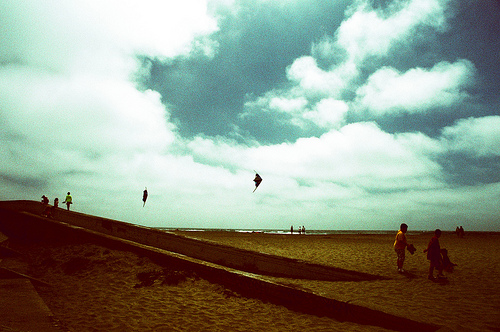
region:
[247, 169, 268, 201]
kite flying in the air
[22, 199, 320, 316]
sand hill in the beach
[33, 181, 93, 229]
people walking on sand hill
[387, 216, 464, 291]
people walking on the beach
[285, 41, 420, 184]
blue sky with white clouds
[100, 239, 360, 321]
large dark shadow on the sand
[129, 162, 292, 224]
two kites on the sky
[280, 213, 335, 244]
people walking in the distance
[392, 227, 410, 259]
person with yellow cotton shirt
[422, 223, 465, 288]
silhouette person on the beach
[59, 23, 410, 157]
lots of clouds in the sky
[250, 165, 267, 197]
a kite in the sky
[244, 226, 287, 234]
water at the edge of the sand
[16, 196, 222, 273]
ramp leading away from the beach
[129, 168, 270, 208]
two kites in the air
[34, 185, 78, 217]
people walking up the ramp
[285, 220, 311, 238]
people standing near the water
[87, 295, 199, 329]
sand at the beach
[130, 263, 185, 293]
weeds growing in the sand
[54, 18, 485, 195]
The sky is partly cloudy.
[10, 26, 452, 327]
It appears to be windy.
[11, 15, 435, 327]
This is on a beach.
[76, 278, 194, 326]
The ground here is sand.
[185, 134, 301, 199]
This is a kite.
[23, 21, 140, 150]
The clouds are white.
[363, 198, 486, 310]
The people are walking.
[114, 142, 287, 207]
The kites are silhouetted.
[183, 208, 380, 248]
There is water in the distance.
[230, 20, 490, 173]
The sky here is blue and white.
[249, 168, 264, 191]
Triangular kite flying in the sky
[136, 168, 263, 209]
Two kites flying in the sky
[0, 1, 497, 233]
White clouds in a bright blue sky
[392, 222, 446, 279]
Two people standing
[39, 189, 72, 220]
Group of people on a hill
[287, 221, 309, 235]
Three people on a shore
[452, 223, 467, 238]
Two people standing together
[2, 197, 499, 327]
Grassy area with concrete pathway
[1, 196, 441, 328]
Small incline with concrete paths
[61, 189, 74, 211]
Person in lime green shirt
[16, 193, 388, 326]
man made structure on beach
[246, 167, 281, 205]
kite flying above the beach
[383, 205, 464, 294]
people playing in the sand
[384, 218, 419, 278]
person on beach with yellow shirt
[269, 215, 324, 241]
people near the water's edge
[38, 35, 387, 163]
white clouds in blue sky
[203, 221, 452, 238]
horizon line between ocean and sky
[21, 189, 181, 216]
people at top of structure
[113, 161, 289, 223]
kites flying above the beach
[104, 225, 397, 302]
wooden beams used to build structure